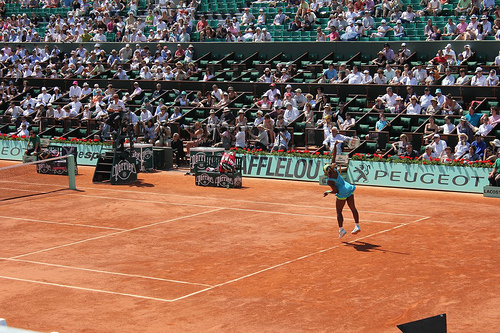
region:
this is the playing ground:
[122, 219, 342, 315]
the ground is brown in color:
[325, 255, 390, 288]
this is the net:
[18, 147, 73, 207]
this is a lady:
[311, 140, 367, 234]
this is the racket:
[337, 130, 362, 150]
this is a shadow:
[353, 234, 383, 259]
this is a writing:
[368, 166, 479, 188]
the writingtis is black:
[380, 165, 429, 187]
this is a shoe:
[335, 228, 351, 235]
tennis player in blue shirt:
[324, 163, 359, 238]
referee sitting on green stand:
[101, 94, 132, 154]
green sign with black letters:
[370, 162, 478, 192]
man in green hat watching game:
[435, 89, 445, 104]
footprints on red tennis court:
[389, 263, 419, 312]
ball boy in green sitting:
[24, 131, 39, 153]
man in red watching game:
[329, 26, 339, 40]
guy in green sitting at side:
[488, 148, 498, 184]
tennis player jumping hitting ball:
[324, 159, 360, 241]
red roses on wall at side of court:
[419, 158, 462, 165]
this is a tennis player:
[319, 149, 366, 235]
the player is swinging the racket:
[323, 147, 360, 241]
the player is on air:
[320, 145, 367, 242]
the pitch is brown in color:
[298, 257, 355, 331]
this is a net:
[25, 152, 65, 198]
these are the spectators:
[351, 63, 446, 128]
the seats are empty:
[223, 52, 248, 78]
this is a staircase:
[95, 145, 125, 184]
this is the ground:
[262, 299, 323, 330]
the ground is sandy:
[257, 287, 303, 309]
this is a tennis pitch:
[23, 200, 270, 275]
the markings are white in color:
[64, 235, 211, 317]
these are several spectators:
[22, 2, 498, 124]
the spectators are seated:
[35, 25, 447, 135]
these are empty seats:
[210, 55, 241, 70]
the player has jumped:
[308, 157, 395, 239]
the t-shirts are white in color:
[287, 112, 292, 117]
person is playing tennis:
[323, 133, 365, 246]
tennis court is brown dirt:
[1, 157, 498, 332]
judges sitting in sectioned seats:
[24, 93, 499, 195]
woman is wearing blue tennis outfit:
[324, 169, 356, 203]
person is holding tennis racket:
[331, 137, 365, 149]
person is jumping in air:
[323, 134, 361, 239]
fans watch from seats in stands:
[0, 0, 497, 162]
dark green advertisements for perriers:
[111, 145, 240, 188]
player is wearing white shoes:
[338, 225, 358, 239]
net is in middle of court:
[0, 154, 75, 204]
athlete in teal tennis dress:
[321, 160, 360, 237]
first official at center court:
[88, 90, 141, 185]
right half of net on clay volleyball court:
[2, 153, 80, 200]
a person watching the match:
[293, 144, 318, 160]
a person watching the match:
[249, 93, 290, 149]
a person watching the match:
[286, 91, 297, 110]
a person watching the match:
[202, 89, 225, 115]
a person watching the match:
[126, 69, 152, 101]